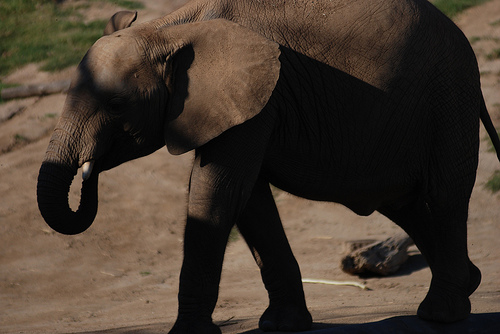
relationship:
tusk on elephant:
[81, 159, 92, 181] [36, 1, 498, 334]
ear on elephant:
[163, 17, 281, 155] [36, 1, 498, 334]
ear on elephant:
[106, 10, 138, 32] [36, 1, 498, 334]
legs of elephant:
[166, 103, 313, 333] [36, 1, 498, 334]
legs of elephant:
[376, 107, 482, 324] [36, 1, 498, 334]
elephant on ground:
[36, 1, 498, 334] [1, 2, 499, 334]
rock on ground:
[342, 235, 414, 277] [1, 2, 499, 334]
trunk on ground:
[1, 79, 70, 99] [1, 2, 499, 334]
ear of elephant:
[163, 17, 281, 155] [36, 1, 498, 334]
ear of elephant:
[106, 10, 138, 32] [36, 1, 498, 334]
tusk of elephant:
[81, 159, 92, 181] [36, 1, 498, 334]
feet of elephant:
[167, 257, 480, 333] [36, 1, 498, 334]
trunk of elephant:
[37, 130, 102, 237] [36, 1, 498, 334]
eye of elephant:
[109, 102, 124, 113] [36, 1, 498, 334]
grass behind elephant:
[0, 0, 498, 199] [36, 1, 498, 334]